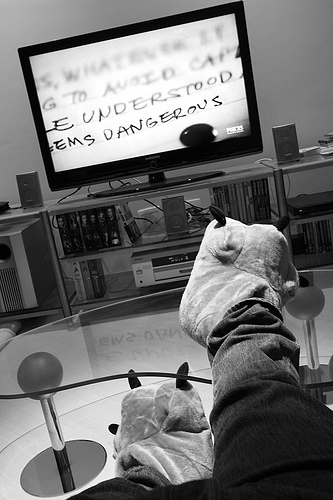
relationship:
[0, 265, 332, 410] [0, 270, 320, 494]
glass top of table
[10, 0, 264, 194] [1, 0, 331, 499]
flat screen in room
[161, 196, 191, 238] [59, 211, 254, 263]
speaker on shelf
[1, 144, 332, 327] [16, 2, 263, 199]
t.v. stand of t.v.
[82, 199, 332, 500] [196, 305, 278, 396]
person wearing jeans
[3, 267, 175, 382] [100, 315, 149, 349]
table on floor glass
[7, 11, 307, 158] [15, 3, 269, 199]
screen on tv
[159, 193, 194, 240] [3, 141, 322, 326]
speaker on table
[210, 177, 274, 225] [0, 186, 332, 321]
dvd under tv stand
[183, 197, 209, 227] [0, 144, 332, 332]
cables behind t.v. stand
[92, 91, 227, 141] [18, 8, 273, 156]
word written on tv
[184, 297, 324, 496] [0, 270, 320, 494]
leg on table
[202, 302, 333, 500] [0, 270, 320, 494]
leg on table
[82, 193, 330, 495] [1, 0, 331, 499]
person in room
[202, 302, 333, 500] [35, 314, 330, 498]
leg in jeans